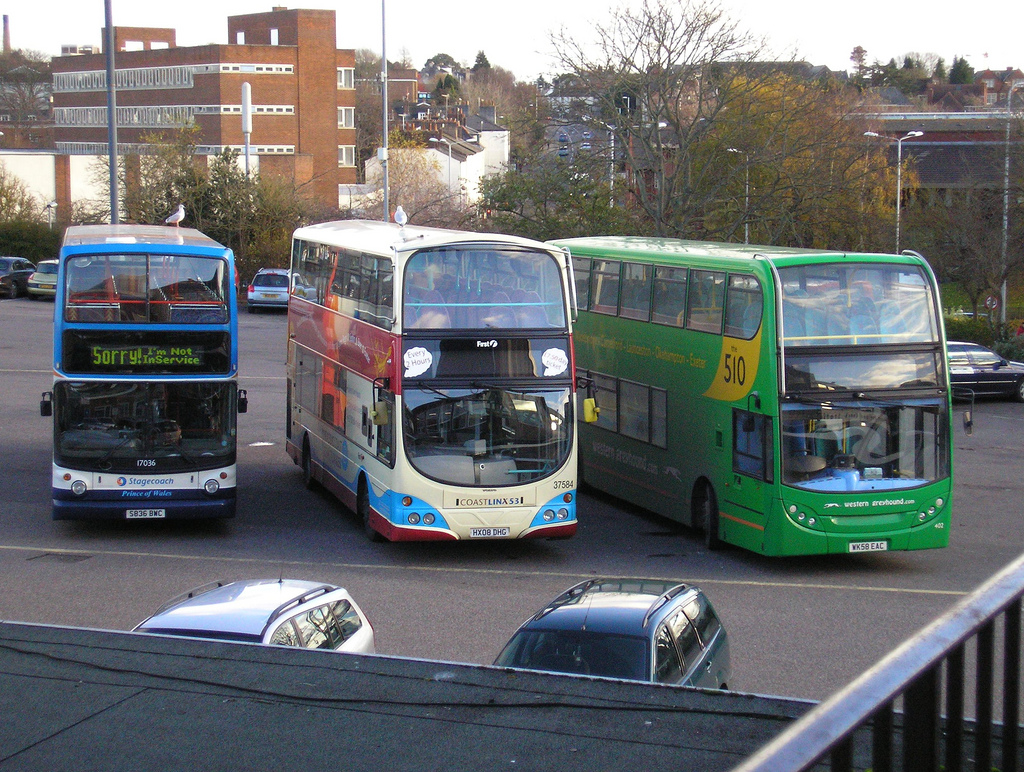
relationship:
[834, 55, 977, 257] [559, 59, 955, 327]
lights behind trees